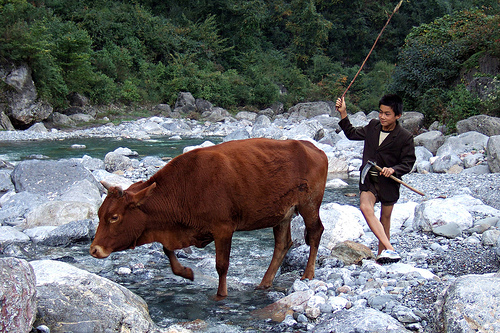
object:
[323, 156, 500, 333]
ground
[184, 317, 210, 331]
pebble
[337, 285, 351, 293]
pebble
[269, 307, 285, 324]
pebble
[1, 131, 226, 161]
pond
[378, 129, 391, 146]
clothing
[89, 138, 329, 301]
brown cow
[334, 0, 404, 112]
whip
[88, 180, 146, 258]
head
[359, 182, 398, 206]
pants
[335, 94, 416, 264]
boy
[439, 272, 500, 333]
rocks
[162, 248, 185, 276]
leg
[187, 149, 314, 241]
fur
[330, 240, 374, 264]
rock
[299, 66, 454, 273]
he's walking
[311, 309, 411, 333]
rocks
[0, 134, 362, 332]
water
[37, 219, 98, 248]
rocks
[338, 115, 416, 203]
blazer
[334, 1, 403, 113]
stick